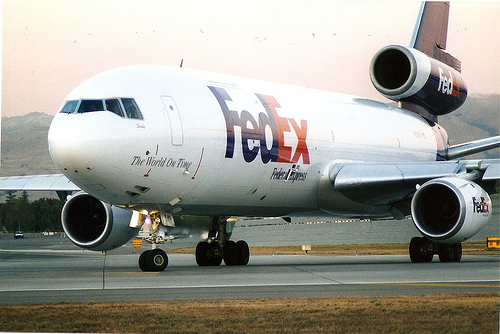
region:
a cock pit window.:
[56, 79, 170, 147]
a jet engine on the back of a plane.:
[360, 39, 472, 119]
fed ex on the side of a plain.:
[203, 77, 314, 179]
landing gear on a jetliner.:
[181, 216, 268, 276]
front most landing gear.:
[120, 191, 185, 276]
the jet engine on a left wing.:
[389, 167, 495, 241]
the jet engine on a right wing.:
[52, 186, 161, 262]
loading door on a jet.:
[161, 71, 194, 145]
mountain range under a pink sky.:
[0, 88, 499, 182]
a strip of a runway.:
[3, 246, 498, 307]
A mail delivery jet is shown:
[16, 7, 494, 324]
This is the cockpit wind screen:
[54, 94, 146, 122]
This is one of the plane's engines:
[406, 171, 498, 242]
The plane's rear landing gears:
[193, 222, 468, 264]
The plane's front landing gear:
[135, 214, 175, 279]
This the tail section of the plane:
[363, 0, 485, 115]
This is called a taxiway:
[8, 259, 498, 295]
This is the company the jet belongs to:
[204, 80, 316, 182]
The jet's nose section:
[41, 115, 150, 196]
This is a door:
[160, 89, 190, 149]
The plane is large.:
[23, 32, 497, 249]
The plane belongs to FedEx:
[185, 73, 327, 198]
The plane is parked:
[35, 48, 497, 292]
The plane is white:
[18, 26, 498, 263]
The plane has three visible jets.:
[60, 11, 499, 287]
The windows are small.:
[36, 78, 147, 133]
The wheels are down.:
[137, 202, 281, 299]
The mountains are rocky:
[7, 79, 54, 201]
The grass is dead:
[50, 271, 267, 326]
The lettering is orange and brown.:
[40, 64, 369, 212]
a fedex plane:
[10, 4, 497, 271]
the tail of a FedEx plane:
[362, 4, 488, 134]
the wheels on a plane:
[116, 193, 287, 296]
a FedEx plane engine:
[328, 143, 498, 260]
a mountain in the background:
[5, 98, 70, 198]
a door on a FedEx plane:
[148, 83, 200, 168]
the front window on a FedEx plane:
[42, 83, 160, 139]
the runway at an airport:
[9, 243, 499, 311]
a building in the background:
[227, 208, 494, 253]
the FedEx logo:
[198, 76, 323, 200]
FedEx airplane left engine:
[408, 177, 495, 242]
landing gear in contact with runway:
[193, 221, 253, 281]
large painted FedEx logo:
[202, 79, 318, 186]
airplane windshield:
[51, 86, 153, 131]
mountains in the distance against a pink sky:
[0, 89, 47, 159]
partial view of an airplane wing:
[0, 171, 84, 196]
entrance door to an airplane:
[153, 86, 194, 151]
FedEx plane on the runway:
[6, 1, 497, 331]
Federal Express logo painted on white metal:
[119, 136, 204, 185]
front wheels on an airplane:
[133, 240, 172, 277]